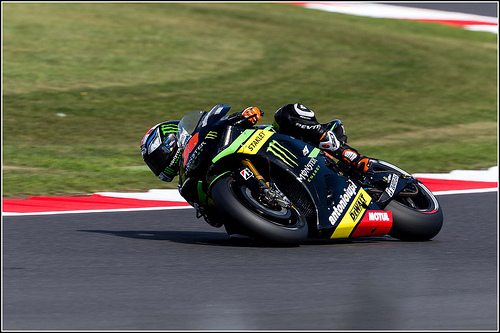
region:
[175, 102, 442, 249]
A motorcycle that is riding very low.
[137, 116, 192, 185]
The helmet of a motorcyclist.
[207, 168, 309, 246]
The tire of a motorcycle.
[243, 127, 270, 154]
A message saying Stakley.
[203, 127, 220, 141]
The logo of Monster energy drink.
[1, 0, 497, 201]
Some beautiful grass inside a racing track.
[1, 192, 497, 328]
The road where a motorcycle is racing.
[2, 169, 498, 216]
A red and white lane.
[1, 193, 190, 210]
The red part of a lane indicating a boundary.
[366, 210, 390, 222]
The logo of the company Motul.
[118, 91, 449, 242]
person riding motorcyle during race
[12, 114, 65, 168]
short green and brown grass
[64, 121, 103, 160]
short green and brown grass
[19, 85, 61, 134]
short green and brown grass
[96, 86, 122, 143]
short green and brown grass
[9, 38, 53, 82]
short green and brown grass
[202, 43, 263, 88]
short green and brown grass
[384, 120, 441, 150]
short green and brown grass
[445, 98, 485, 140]
short green and brown grass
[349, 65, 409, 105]
short green and brown grass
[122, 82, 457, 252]
black motorcycle on cement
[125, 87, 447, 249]
man riding a motorcycle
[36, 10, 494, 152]
short green grass on lawn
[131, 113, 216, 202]
man wearing a helmet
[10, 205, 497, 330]
smooth black cement road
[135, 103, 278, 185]
man wearing orange glove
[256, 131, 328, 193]
green sticker on motorcycle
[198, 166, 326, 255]
smooth black tire of motorcycle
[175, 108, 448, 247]
motorcycle leaning toward ground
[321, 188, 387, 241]
yellow sticker on motorcycle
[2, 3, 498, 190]
a large area of green grass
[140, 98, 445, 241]
someone riding a motorcycle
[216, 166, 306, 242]
the front wheel on the motorcycle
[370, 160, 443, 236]
the back wheel on the motorcycle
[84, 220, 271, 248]
the shadow on the ground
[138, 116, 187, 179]
the helmet on the motorcycle rider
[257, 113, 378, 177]
the left leg of the motorcycle rider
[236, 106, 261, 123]
the glove on the left hand of the motorcycle rider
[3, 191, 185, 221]
the red area on the ground near the motorcycle rider's head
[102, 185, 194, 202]
the white are on the ground near the motorcycle rider's head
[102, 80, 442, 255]
person riding a motorcycle on a track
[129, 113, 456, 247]
person leaning over on motorcycle to turn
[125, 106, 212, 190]
person wearing a motorcycle safety helmet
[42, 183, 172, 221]
red and white boundary surrounding track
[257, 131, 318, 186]
Monster logo on side of motorcycle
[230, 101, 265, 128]
rider weearing orange gloves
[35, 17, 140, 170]
green grass in the infield of track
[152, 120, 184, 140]
Monster logo on side of motorcycle helmet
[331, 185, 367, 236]
yellow DeWalt logo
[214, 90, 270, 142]
rider holding on to handlebar